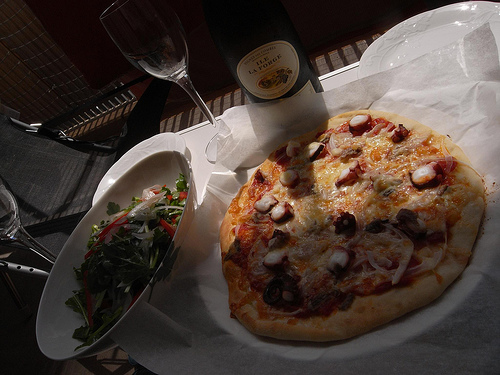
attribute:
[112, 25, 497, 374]
paper — white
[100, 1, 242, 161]
glass — empty 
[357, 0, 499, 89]
plate — white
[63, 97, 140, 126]
metal grating — black 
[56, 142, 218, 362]
salad — green red & white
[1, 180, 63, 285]
glass — empty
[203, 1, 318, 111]
bottle — dark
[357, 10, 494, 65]
plate — white 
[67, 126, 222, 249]
plate — white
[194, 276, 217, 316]
plate — white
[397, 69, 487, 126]
paper — white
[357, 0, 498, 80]
plate — white 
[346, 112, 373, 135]
topping — purple, white